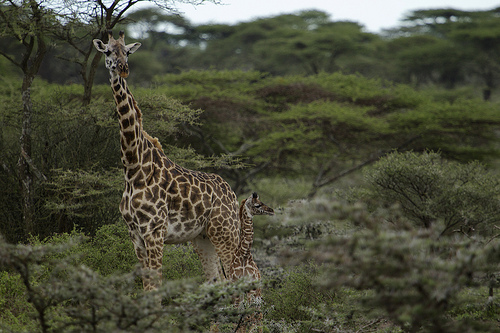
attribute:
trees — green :
[134, 22, 426, 252]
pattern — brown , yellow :
[141, 145, 189, 212]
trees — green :
[235, 79, 308, 143]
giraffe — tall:
[86, 43, 292, 325]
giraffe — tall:
[54, 20, 292, 330]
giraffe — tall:
[74, 18, 244, 308]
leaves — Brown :
[225, 52, 392, 173]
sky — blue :
[175, 7, 405, 62]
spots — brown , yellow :
[154, 179, 228, 228]